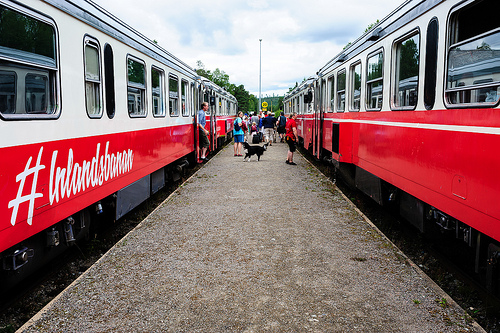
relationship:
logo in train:
[12, 137, 141, 229] [3, 0, 247, 260]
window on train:
[3, 9, 68, 128] [0, 0, 237, 286]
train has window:
[0, 0, 237, 286] [77, 25, 111, 126]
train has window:
[7, 14, 233, 321] [104, 45, 123, 117]